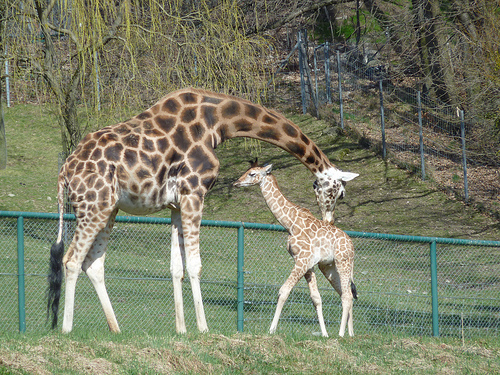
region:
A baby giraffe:
[232, 156, 363, 336]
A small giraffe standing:
[231, 160, 361, 347]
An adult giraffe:
[18, 68, 354, 345]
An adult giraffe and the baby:
[18, 59, 375, 349]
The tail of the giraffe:
[46, 166, 68, 331]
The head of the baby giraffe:
[230, 158, 275, 190]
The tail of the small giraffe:
[348, 251, 363, 304]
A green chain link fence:
[366, 232, 499, 334]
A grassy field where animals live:
[48, 344, 488, 370]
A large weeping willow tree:
[3, 1, 273, 112]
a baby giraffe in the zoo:
[232, 155, 362, 340]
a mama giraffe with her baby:
[42, 78, 362, 343]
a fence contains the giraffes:
[1, 203, 499, 352]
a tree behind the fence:
[5, 1, 283, 253]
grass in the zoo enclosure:
[6, 324, 499, 369]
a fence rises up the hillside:
[267, 23, 495, 215]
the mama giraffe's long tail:
[46, 155, 74, 332]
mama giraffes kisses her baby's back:
[307, 140, 361, 236]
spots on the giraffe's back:
[101, 133, 190, 190]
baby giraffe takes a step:
[231, 155, 361, 340]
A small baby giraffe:
[230, 162, 361, 342]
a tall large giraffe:
[47, 87, 360, 337]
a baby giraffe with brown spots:
[232, 163, 359, 340]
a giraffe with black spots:
[46, 86, 358, 344]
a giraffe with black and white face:
[311, 169, 360, 226]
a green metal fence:
[0, 208, 499, 345]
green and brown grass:
[0, 332, 499, 373]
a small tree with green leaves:
[2, 0, 279, 212]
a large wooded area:
[0, 1, 499, 215]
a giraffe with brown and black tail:
[45, 174, 65, 335]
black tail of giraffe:
[45, 228, 61, 335]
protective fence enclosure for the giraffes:
[220, 218, 255, 278]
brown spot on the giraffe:
[117, 136, 147, 147]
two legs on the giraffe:
[165, 213, 209, 342]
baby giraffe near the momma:
[234, 158, 365, 349]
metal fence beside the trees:
[377, 90, 442, 161]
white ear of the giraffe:
[338, 162, 360, 187]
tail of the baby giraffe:
[349, 275, 361, 299]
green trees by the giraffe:
[32, 57, 113, 121]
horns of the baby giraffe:
[243, 153, 260, 167]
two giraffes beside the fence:
[53, 75, 396, 342]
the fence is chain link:
[13, 211, 498, 348]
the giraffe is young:
[231, 160, 371, 341]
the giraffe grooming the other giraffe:
[59, 128, 356, 352]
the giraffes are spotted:
[50, 81, 396, 335]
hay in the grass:
[162, 340, 351, 374]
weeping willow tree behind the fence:
[35, 5, 241, 62]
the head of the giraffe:
[311, 159, 364, 216]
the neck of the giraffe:
[199, 85, 324, 168]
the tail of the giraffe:
[46, 188, 73, 332]